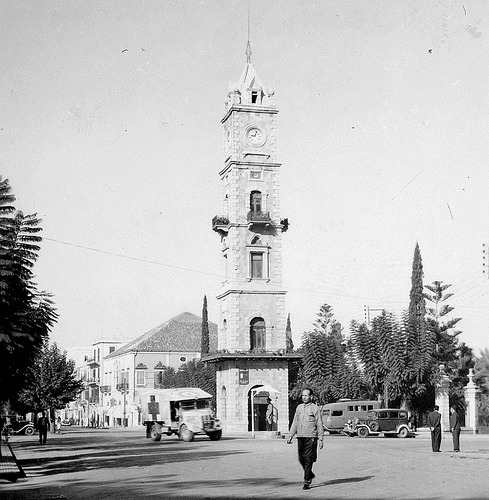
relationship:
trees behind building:
[268, 264, 466, 454] [209, 0, 290, 440]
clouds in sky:
[222, 37, 368, 171] [33, 29, 487, 318]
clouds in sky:
[0, 0, 488, 368] [2, 3, 486, 335]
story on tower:
[202, 354, 301, 435] [204, 5, 299, 433]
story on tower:
[216, 290, 288, 353] [204, 5, 299, 433]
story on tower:
[211, 220, 289, 292] [204, 5, 299, 433]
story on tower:
[219, 164, 283, 222] [204, 5, 299, 433]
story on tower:
[222, 105, 278, 161] [204, 5, 299, 433]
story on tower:
[217, 61, 281, 109] [204, 5, 299, 433]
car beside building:
[342, 406, 414, 441] [200, 3, 299, 438]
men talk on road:
[425, 403, 461, 453] [0, 425, 487, 496]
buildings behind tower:
[47, 307, 246, 482] [123, 31, 374, 498]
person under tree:
[287, 387, 325, 490] [18, 349, 57, 413]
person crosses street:
[287, 387, 325, 490] [0, 426, 489, 498]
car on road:
[342, 406, 414, 437] [18, 425, 486, 497]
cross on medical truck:
[142, 393, 165, 420] [137, 384, 223, 442]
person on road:
[287, 387, 325, 490] [49, 363, 482, 488]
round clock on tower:
[244, 124, 265, 148] [202, 2, 292, 436]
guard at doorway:
[263, 393, 273, 428] [247, 384, 272, 432]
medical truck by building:
[137, 384, 230, 442] [202, 67, 298, 429]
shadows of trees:
[15, 423, 367, 499] [1, 183, 73, 497]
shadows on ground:
[15, 423, 367, 499] [4, 417, 487, 499]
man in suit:
[447, 403, 467, 454] [452, 414, 462, 446]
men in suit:
[425, 403, 441, 455] [428, 411, 445, 451]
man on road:
[447, 403, 467, 454] [18, 425, 486, 497]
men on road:
[425, 403, 441, 455] [18, 425, 486, 497]